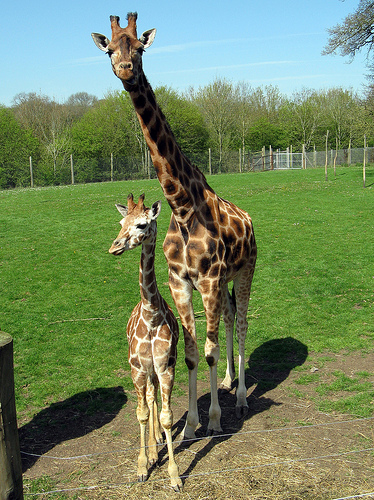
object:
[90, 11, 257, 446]
giraffe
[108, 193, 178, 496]
giraffe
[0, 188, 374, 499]
grass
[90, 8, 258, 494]
giraffes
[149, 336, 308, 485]
shadow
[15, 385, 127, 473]
shadow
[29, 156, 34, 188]
post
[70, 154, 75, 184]
post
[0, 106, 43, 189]
tree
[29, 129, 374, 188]
fence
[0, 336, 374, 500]
patch of dirt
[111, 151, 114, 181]
post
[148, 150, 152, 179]
post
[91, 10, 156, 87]
head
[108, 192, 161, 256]
head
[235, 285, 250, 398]
leg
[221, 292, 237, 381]
leg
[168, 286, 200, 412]
leg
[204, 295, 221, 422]
leg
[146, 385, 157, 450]
leg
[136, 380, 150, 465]
leg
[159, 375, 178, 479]
leg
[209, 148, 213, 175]
post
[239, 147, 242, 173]
post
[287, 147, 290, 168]
post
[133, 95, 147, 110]
spot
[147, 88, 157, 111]
spot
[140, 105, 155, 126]
spot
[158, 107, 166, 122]
spot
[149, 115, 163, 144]
spot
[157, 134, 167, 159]
spot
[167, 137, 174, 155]
spot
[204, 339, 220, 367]
knee